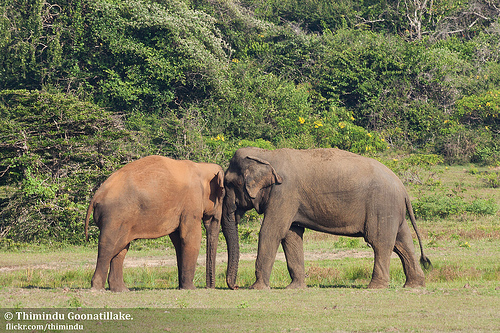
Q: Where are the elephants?
A: In the grass.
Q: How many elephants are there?
A: Two.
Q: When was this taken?
A: Daytime.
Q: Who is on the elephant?
A: No one.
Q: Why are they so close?
A: They love each other.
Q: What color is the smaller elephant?
A: Brown.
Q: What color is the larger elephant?
A: Grey.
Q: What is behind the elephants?
A: Trees and bushes.